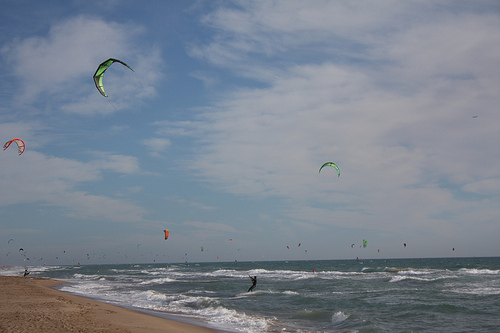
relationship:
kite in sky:
[87, 53, 137, 98] [142, 20, 291, 168]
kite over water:
[87, 53, 137, 98] [25, 255, 500, 330]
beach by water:
[5, 277, 198, 328] [25, 255, 500, 330]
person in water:
[237, 273, 263, 297] [25, 255, 500, 330]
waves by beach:
[90, 282, 267, 332] [5, 277, 198, 328]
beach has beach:
[5, 277, 198, 328] [0, 275, 217, 333]